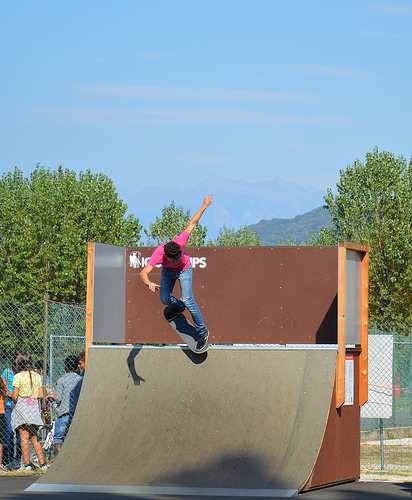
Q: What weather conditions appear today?
A: It is clear.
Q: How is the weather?
A: It is clear.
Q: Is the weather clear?
A: Yes, it is clear.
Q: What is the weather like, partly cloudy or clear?
A: It is clear.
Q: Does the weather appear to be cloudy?
A: No, it is clear.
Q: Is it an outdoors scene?
A: Yes, it is outdoors.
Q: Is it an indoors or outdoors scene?
A: It is outdoors.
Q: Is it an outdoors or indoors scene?
A: It is outdoors.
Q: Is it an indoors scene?
A: No, it is outdoors.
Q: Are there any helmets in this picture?
A: No, there are no helmets.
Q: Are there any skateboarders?
A: Yes, there is a skateboarder.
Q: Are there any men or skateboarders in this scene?
A: Yes, there is a skateboarder.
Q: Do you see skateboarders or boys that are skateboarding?
A: Yes, the skateboarder is skateboarding.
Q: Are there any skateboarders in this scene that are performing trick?
A: Yes, there is a skateboarder that is performing trick.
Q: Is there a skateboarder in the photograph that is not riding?
A: Yes, there is a skateboarder that is performing trick.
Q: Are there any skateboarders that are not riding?
A: Yes, there is a skateboarder that is performing trick.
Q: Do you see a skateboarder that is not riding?
A: Yes, there is a skateboarder that is performing trick .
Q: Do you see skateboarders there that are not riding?
A: Yes, there is a skateboarder that is performing trick .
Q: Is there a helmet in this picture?
A: No, there are no helmets.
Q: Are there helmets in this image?
A: No, there are no helmets.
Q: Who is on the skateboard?
A: The skateboarder is on the skateboard.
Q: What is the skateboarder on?
A: The skateboarder is on the skateboard.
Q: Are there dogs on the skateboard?
A: No, there is a skateboarder on the skateboard.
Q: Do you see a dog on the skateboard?
A: No, there is a skateboarder on the skateboard.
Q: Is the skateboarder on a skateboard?
A: Yes, the skateboarder is on a skateboard.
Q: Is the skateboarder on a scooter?
A: No, the skateboarder is on a skateboard.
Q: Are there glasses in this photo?
A: No, there are no glasses.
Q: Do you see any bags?
A: No, there are no bags.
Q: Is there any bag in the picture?
A: No, there are no bags.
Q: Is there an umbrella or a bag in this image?
A: No, there are no bags or umbrellas.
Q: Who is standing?
A: The people are standing.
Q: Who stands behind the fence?
A: The people stand behind the fence.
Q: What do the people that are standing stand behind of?
A: The people stand behind the fence.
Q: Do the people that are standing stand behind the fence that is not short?
A: Yes, the people stand behind the fence.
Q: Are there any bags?
A: No, there are no bags.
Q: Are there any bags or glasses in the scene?
A: No, there are no bags or glasses.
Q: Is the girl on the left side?
A: Yes, the girl is on the left of the image.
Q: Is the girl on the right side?
A: No, the girl is on the left of the image.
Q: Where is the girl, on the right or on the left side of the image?
A: The girl is on the left of the image.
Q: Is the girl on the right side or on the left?
A: The girl is on the left of the image.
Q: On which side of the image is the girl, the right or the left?
A: The girl is on the left of the image.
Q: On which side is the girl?
A: The girl is on the left of the image.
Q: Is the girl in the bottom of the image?
A: Yes, the girl is in the bottom of the image.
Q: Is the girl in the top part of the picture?
A: No, the girl is in the bottom of the image.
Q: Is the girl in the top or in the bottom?
A: The girl is in the bottom of the image.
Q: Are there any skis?
A: No, there are no skis.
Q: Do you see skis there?
A: No, there are no skis.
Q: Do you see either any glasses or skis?
A: No, there are no skis or glasses.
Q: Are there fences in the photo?
A: Yes, there is a fence.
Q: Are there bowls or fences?
A: Yes, there is a fence.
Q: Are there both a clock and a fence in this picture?
A: No, there is a fence but no clocks.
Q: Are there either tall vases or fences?
A: Yes, there is a tall fence.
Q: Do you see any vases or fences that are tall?
A: Yes, the fence is tall.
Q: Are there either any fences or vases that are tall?
A: Yes, the fence is tall.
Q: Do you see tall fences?
A: Yes, there is a tall fence.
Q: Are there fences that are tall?
A: Yes, there is a fence that is tall.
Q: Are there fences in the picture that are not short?
A: Yes, there is a tall fence.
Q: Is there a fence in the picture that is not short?
A: Yes, there is a tall fence.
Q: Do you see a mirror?
A: No, there are no mirrors.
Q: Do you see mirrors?
A: No, there are no mirrors.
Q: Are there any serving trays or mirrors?
A: No, there are no mirrors or serving trays.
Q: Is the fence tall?
A: Yes, the fence is tall.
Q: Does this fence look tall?
A: Yes, the fence is tall.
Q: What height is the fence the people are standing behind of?
A: The fence is tall.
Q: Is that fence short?
A: No, the fence is tall.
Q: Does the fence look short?
A: No, the fence is tall.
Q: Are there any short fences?
A: No, there is a fence but it is tall.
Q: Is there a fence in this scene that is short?
A: No, there is a fence but it is tall.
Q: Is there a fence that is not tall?
A: No, there is a fence but it is tall.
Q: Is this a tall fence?
A: Yes, this is a tall fence.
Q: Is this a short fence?
A: No, this is a tall fence.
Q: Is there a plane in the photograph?
A: No, there are no airplanes.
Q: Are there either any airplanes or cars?
A: No, there are no airplanes or cars.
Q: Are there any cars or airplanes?
A: No, there are no airplanes or cars.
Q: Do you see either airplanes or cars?
A: No, there are no airplanes or cars.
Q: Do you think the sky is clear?
A: Yes, the sky is clear.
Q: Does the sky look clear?
A: Yes, the sky is clear.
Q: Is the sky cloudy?
A: No, the sky is clear.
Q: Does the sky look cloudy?
A: No, the sky is clear.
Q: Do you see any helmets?
A: No, there are no helmets.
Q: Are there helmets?
A: No, there are no helmets.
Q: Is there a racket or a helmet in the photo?
A: No, there are no helmets or rackets.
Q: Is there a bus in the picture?
A: No, there are no buses.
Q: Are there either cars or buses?
A: No, there are no buses or cars.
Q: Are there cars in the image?
A: No, there are no cars.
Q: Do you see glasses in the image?
A: No, there are no glasses.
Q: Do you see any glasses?
A: No, there are no glasses.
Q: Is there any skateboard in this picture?
A: Yes, there is a skateboard.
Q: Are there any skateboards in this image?
A: Yes, there is a skateboard.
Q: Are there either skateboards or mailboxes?
A: Yes, there is a skateboard.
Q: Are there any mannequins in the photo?
A: No, there are no mannequins.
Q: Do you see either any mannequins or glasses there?
A: No, there are no mannequins or glasses.